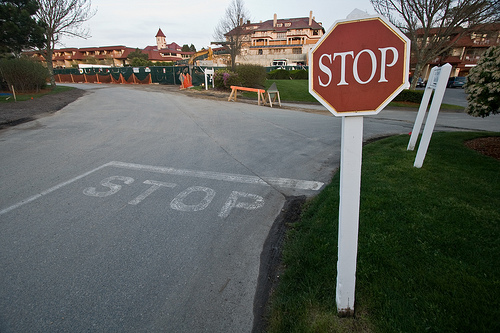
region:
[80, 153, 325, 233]
Stop written in white paint on the street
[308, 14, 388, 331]
Red and white stop sign on the right side of a street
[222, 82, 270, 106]
Construction barrier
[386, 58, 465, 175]
White sign on the corner of a street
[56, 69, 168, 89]
Orange netting on a construction site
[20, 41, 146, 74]
Apartment building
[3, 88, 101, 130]
Muddy area on the left side of the street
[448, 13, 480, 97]
Car parked in a lot in front of a building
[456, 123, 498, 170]
Mulched area in a lawn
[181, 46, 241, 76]
Yellow construction vehicle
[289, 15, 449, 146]
Stop sign on the road.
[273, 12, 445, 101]
Red stop sign with white letters.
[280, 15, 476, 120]
White letters on the red sign.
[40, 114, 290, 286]
White stop on the road.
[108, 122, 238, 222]
White line on the road.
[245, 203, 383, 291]
Grass by the road.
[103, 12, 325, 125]
Buildings in the background.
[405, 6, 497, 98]
Tree in the background.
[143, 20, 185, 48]
Tower on the building.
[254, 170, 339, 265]
Water on the road.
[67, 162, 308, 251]
"Stop" written on the road.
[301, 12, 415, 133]
Stop sign by the curb.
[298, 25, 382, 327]
Stop sign is made of wood.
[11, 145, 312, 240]
White lines on the ground.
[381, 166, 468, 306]
The grass is green.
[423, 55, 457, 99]
Sign in a frame.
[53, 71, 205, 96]
An orange construction fence.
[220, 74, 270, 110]
An orange construction gate.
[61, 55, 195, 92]
Green gate around construction.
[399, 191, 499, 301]
The grass is green.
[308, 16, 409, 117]
red stop sign with white letters and a gold border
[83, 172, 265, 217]
stop sign on the ground in worn white lettering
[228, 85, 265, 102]
sawhorse with a bright orange cross beam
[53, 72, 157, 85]
bright orange construction markers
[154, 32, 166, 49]
tower with tan walls and a red roof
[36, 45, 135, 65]
multi-unit structure in the background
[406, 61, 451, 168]
white wood sign that leans backward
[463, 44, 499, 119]
edge of a large blooming tree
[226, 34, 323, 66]
large stone commercial building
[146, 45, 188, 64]
red roof of the apartment building or hotel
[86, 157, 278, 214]
some writing on the road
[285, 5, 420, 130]
a red and white sign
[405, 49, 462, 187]
a sign between fence posts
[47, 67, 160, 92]
a few orange cones and net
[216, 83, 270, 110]
an orange and wood barrier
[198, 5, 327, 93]
a large distant building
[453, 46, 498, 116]
a bunch of flowers on a tree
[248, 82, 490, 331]
a lawn near the road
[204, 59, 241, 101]
a shrub with purple flowers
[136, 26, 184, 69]
a red roofed building